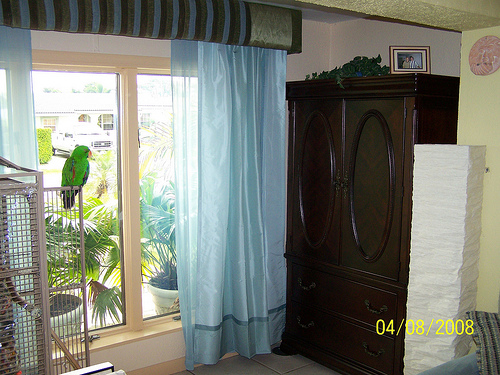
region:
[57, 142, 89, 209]
a green parrot bird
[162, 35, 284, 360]
a long blue curtain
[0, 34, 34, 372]
a long blue curtain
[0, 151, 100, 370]
a metal bird cage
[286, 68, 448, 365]
a dark wood dresser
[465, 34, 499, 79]
a piece of artwork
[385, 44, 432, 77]
a small framed photo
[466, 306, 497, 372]
a black striped pillow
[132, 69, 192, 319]
a wall length window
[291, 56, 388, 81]
a piece of greenery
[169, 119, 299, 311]
the curtain is blue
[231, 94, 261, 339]
the curtain is blue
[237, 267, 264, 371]
the curtain is blue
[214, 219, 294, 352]
the curtain is blue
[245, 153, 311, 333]
the curtain is blue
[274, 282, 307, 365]
the curtain is blue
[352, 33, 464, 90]
gold picture frame with picture of two people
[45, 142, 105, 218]
green bird with yellow beak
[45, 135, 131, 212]
bird with green feathers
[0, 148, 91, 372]
large gray bird cage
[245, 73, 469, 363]
large piece of wooden furniture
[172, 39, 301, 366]
blue sheer curtains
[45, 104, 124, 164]
vehicle parked outside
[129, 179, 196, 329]
plant in white planter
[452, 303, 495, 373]
cushion lying on a sofa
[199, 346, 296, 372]
tan floor tile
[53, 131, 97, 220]
A green bird standing on a cage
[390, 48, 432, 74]
A picture of a couple.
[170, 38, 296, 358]
Hanging blue drapes.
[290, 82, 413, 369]
A brown wooden wardrobe.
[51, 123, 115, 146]
A white truck in a driveway.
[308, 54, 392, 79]
A green plant on top of the brown wooden wardrobe.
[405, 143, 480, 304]
A white lamp shade.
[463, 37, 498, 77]
A terracota wall hanging.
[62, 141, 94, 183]
A green parrot.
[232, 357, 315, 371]
a white tile floor.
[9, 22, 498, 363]
An interior room scene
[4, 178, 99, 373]
A bird cage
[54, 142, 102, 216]
A parrot is sitting on the cage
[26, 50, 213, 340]
A large window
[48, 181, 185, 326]
Potted plants are outside the window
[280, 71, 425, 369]
This is a wooden cabinet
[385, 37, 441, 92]
A framed photo is on top the cabinet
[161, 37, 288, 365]
The curtains are blue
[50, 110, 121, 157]
A truck is parked outside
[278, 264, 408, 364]
The cabinet has drawers